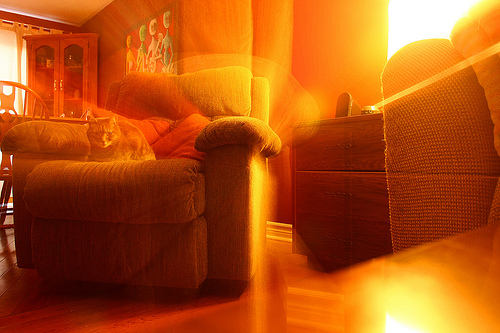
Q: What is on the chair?
A: A cat.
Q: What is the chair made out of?
A: Fabric.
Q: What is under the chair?
A: A wood floor.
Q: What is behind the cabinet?
A: A window.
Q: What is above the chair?
A: A picture.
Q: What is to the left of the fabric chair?
A: A wooden chair.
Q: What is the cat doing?
A: Sitting.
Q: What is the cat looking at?
A: The camera.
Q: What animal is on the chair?
A: Cat.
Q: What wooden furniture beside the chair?
A: Table.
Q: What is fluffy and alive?
A: The cat.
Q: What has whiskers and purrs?
A: A cat.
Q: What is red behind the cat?
A: Pillows.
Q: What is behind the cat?
A: Pillows.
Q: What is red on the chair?
A: Pillows.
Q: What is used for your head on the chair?
A: Pillows.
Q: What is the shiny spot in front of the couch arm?
A: A glare.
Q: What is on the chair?
A: A cat.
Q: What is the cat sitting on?
A: A chair.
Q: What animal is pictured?
A: A cat.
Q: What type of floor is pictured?
A: Wood floor.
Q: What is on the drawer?
A: A speaker.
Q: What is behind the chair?
A: A picture.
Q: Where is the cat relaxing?
A: On the chair.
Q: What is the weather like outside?
A: Sunny.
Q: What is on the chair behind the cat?
A: A pillow.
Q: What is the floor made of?
A: Wood.